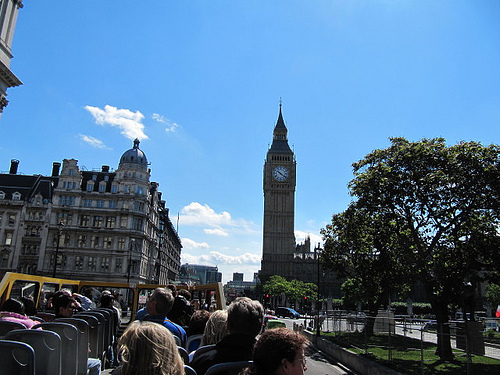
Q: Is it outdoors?
A: Yes, it is outdoors.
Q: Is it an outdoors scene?
A: Yes, it is outdoors.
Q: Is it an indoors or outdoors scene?
A: It is outdoors.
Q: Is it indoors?
A: No, it is outdoors.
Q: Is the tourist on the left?
A: Yes, the tourist is on the left of the image.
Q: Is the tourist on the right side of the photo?
A: No, the tourist is on the left of the image.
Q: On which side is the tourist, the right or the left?
A: The tourist is on the left of the image.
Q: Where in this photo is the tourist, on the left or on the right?
A: The tourist is on the left of the image.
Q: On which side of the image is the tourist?
A: The tourist is on the left of the image.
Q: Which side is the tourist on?
A: The tourist is on the left of the image.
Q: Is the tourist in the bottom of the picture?
A: Yes, the tourist is in the bottom of the image.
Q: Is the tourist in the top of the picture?
A: No, the tourist is in the bottom of the image.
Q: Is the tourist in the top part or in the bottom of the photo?
A: The tourist is in the bottom of the image.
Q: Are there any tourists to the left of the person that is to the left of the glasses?
A: Yes, there is a tourist to the left of the person.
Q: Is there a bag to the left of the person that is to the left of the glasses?
A: No, there is a tourist to the left of the person.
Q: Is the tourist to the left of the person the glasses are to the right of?
A: Yes, the tourist is to the left of the person.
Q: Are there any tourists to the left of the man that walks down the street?
A: Yes, there is a tourist to the left of the man.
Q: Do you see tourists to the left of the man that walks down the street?
A: Yes, there is a tourist to the left of the man.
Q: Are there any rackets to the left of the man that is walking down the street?
A: No, there is a tourist to the left of the man.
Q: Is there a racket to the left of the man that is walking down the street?
A: No, there is a tourist to the left of the man.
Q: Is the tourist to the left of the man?
A: Yes, the tourist is to the left of the man.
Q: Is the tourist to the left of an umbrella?
A: No, the tourist is to the left of the man.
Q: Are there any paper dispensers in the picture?
A: No, there are no paper dispensers.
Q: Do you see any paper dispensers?
A: No, there are no paper dispensers.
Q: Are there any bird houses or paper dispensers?
A: No, there are no paper dispensers or bird houses.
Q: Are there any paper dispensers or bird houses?
A: No, there are no paper dispensers or bird houses.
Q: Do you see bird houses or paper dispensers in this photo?
A: No, there are no paper dispensers or bird houses.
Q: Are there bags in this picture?
A: No, there are no bags.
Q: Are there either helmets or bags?
A: No, there are no bags or helmets.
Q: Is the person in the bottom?
A: Yes, the person is in the bottom of the image.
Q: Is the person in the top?
A: No, the person is in the bottom of the image.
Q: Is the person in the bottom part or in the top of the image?
A: The person is in the bottom of the image.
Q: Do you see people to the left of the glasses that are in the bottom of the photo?
A: Yes, there is a person to the left of the glasses.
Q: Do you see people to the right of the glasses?
A: No, the person is to the left of the glasses.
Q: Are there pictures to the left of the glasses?
A: No, there is a person to the left of the glasses.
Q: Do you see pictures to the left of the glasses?
A: No, there is a person to the left of the glasses.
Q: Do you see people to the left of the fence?
A: Yes, there is a person to the left of the fence.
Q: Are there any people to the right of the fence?
A: No, the person is to the left of the fence.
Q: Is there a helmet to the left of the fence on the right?
A: No, there is a person to the left of the fence.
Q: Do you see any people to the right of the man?
A: Yes, there is a person to the right of the man.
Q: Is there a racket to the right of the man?
A: No, there is a person to the right of the man.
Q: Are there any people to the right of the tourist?
A: Yes, there is a person to the right of the tourist.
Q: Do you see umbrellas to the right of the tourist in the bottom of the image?
A: No, there is a person to the right of the tourist.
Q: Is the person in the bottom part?
A: Yes, the person is in the bottom of the image.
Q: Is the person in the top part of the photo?
A: No, the person is in the bottom of the image.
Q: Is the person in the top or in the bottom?
A: The person is in the bottom of the image.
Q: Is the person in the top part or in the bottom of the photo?
A: The person is in the bottom of the image.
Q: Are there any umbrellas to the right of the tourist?
A: No, there is a person to the right of the tourist.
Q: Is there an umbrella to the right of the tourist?
A: No, there is a person to the right of the tourist.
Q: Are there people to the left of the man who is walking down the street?
A: Yes, there is a person to the left of the man.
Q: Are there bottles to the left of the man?
A: No, there is a person to the left of the man.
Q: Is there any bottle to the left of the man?
A: No, there is a person to the left of the man.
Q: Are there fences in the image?
A: Yes, there is a fence.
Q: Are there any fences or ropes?
A: Yes, there is a fence.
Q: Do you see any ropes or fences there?
A: Yes, there is a fence.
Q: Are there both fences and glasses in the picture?
A: Yes, there are both a fence and glasses.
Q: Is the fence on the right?
A: Yes, the fence is on the right of the image.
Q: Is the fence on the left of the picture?
A: No, the fence is on the right of the image.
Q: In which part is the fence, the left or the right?
A: The fence is on the right of the image.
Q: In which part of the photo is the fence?
A: The fence is on the right of the image.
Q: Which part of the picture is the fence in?
A: The fence is on the right of the image.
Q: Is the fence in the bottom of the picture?
A: Yes, the fence is in the bottom of the image.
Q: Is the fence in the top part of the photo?
A: No, the fence is in the bottom of the image.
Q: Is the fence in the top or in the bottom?
A: The fence is in the bottom of the image.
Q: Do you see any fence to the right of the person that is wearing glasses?
A: Yes, there is a fence to the right of the person.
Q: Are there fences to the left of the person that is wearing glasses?
A: No, the fence is to the right of the person.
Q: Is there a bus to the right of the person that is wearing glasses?
A: No, there is a fence to the right of the person.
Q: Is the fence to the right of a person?
A: Yes, the fence is to the right of a person.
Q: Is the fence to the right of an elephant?
A: No, the fence is to the right of a person.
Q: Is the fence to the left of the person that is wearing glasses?
A: No, the fence is to the right of the person.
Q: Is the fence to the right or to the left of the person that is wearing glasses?
A: The fence is to the right of the person.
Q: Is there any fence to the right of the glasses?
A: Yes, there is a fence to the right of the glasses.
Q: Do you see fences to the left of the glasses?
A: No, the fence is to the right of the glasses.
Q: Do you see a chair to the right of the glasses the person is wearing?
A: No, there is a fence to the right of the glasses.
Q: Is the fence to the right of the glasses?
A: Yes, the fence is to the right of the glasses.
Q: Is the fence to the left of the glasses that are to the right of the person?
A: No, the fence is to the right of the glasses.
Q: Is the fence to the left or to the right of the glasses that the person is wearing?
A: The fence is to the right of the glasses.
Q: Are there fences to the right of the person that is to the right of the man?
A: Yes, there is a fence to the right of the person.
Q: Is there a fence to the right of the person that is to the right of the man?
A: Yes, there is a fence to the right of the person.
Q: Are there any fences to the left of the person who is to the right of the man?
A: No, the fence is to the right of the person.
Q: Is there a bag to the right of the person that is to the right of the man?
A: No, there is a fence to the right of the person.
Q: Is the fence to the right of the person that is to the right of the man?
A: Yes, the fence is to the right of the person.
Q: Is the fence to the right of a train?
A: No, the fence is to the right of the person.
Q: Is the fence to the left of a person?
A: No, the fence is to the right of a person.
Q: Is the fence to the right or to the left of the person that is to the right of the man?
A: The fence is to the right of the person.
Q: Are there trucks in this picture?
A: No, there are no trucks.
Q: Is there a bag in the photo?
A: No, there are no bags.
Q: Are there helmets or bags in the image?
A: No, there are no bags or helmets.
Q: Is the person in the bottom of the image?
A: Yes, the person is in the bottom of the image.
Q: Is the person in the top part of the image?
A: No, the person is in the bottom of the image.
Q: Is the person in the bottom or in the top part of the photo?
A: The person is in the bottom of the image.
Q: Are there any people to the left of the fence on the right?
A: Yes, there is a person to the left of the fence.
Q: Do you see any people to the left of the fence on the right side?
A: Yes, there is a person to the left of the fence.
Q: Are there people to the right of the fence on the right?
A: No, the person is to the left of the fence.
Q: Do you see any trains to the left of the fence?
A: No, there is a person to the left of the fence.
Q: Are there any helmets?
A: No, there are no helmets.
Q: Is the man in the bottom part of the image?
A: Yes, the man is in the bottom of the image.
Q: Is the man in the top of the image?
A: No, the man is in the bottom of the image.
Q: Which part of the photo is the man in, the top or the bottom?
A: The man is in the bottom of the image.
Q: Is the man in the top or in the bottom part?
A: The man is in the bottom of the image.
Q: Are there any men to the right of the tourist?
A: Yes, there is a man to the right of the tourist.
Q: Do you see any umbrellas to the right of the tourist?
A: No, there is a man to the right of the tourist.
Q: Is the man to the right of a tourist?
A: Yes, the man is to the right of a tourist.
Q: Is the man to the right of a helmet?
A: No, the man is to the right of a tourist.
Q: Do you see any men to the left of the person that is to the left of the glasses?
A: Yes, there is a man to the left of the person.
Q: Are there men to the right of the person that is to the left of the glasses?
A: No, the man is to the left of the person.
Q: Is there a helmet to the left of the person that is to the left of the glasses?
A: No, there is a man to the left of the person.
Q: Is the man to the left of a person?
A: Yes, the man is to the left of a person.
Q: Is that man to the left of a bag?
A: No, the man is to the left of a person.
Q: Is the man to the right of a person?
A: No, the man is to the left of a person.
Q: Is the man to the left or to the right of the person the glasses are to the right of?
A: The man is to the left of the person.